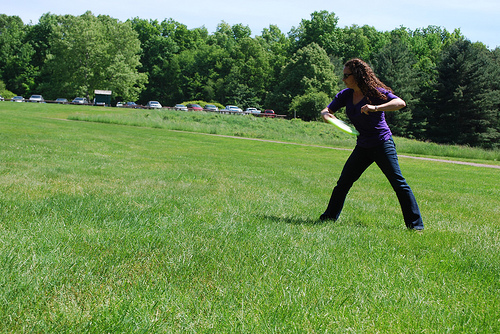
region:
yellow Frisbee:
[324, 99, 348, 138]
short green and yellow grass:
[39, 118, 75, 158]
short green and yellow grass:
[141, 166, 169, 197]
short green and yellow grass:
[46, 197, 96, 234]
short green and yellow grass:
[181, 180, 218, 223]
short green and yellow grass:
[256, 270, 298, 308]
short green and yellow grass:
[315, 276, 363, 307]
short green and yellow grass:
[96, 199, 146, 245]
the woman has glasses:
[310, 57, 446, 237]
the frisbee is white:
[315, 107, 361, 137]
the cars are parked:
[22, 78, 285, 118]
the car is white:
[146, 97, 163, 112]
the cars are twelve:
[8, 85, 284, 127]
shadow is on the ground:
[263, 200, 312, 232]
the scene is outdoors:
[6, 13, 489, 329]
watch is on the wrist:
[363, 95, 385, 117]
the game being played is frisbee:
[1, 28, 489, 325]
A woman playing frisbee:
[316, 55, 432, 238]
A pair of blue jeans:
[321, 135, 426, 231]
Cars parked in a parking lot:
[9, 86, 279, 122]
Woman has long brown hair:
[339, 55, 397, 105]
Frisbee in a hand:
[316, 103, 356, 139]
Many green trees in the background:
[1, 6, 499, 153]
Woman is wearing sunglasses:
[334, 59, 372, 91]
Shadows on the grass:
[261, 209, 405, 238]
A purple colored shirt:
[323, 55, 401, 141]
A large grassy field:
[1, 99, 497, 330]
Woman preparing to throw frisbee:
[315, 58, 430, 235]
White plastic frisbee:
[321, 106, 355, 138]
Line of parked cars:
[8, 91, 290, 121]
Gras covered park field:
[8, 103, 493, 328]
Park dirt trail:
[393, 146, 494, 174]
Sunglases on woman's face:
[338, 71, 365, 82]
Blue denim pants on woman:
[305, 137, 427, 234]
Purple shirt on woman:
[323, 86, 398, 138]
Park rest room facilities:
[92, 87, 114, 105]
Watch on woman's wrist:
[372, 105, 381, 114]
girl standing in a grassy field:
[320, 52, 425, 249]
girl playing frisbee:
[315, 51, 410, 131]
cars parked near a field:
[0, 85, 285, 120]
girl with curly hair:
[341, 55, 393, 108]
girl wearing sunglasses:
[341, 70, 349, 79]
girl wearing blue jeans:
[316, 137, 428, 239]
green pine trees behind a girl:
[368, 34, 496, 154]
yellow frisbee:
[323, 116, 361, 136]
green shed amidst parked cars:
[88, 85, 113, 111]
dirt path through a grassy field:
[185, 129, 498, 173]